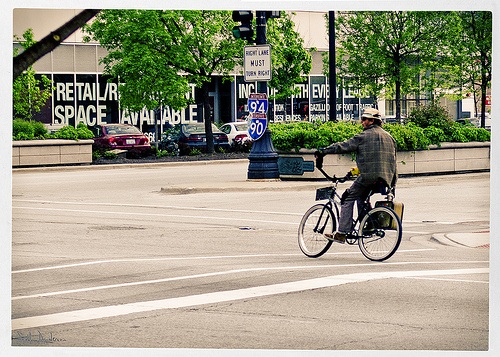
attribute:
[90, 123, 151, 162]
car — parked, red, compact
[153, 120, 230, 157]
car — parked, blue, small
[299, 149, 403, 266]
bike — black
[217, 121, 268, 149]
car — parked, white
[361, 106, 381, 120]
hat — white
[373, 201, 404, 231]
briefcase — yellow, black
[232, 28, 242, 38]
light — green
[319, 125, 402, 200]
jacket — gray, plaid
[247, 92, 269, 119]
sign — blue, white